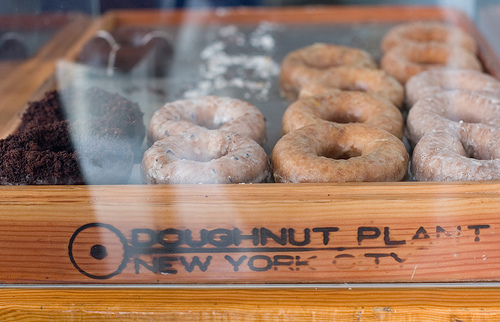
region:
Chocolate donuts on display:
[10, 51, 141, 227]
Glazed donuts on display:
[264, 37, 417, 229]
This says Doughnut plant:
[128, 212, 498, 274]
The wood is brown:
[11, 206, 118, 318]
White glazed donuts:
[144, 68, 286, 210]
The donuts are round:
[274, 37, 356, 186]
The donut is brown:
[6, 89, 129, 189]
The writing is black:
[109, 208, 402, 293]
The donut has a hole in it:
[311, 133, 386, 176]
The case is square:
[14, 6, 484, 295]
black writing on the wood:
[131, 210, 491, 251]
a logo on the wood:
[63, 213, 133, 282]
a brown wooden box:
[0, 0, 498, 279]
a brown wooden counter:
[0, 286, 497, 320]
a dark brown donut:
[0, 112, 141, 187]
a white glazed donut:
[136, 122, 266, 187]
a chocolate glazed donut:
[77, 21, 180, 76]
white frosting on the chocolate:
[101, 42, 122, 77]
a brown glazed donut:
[273, 117, 412, 192]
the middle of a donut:
[313, 137, 363, 164]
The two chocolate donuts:
[1, 84, 148, 189]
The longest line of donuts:
[378, 18, 498, 183]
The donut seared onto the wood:
[66, 222, 132, 282]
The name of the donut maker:
[127, 217, 494, 252]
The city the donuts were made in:
[124, 247, 414, 279]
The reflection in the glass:
[49, 0, 466, 279]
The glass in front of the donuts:
[0, 1, 499, 282]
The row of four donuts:
[272, 36, 412, 186]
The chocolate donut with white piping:
[79, 16, 175, 84]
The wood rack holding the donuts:
[0, 5, 499, 286]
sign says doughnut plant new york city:
[119, 208, 487, 293]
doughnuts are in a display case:
[13, 6, 493, 314]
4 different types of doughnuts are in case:
[2, 53, 498, 296]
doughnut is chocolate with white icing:
[60, 13, 215, 107]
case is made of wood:
[10, 29, 492, 268]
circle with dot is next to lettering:
[55, 217, 167, 289]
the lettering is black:
[119, 220, 498, 310]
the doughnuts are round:
[165, 6, 496, 190]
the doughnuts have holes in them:
[161, 6, 477, 221]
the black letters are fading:
[295, 224, 496, 296]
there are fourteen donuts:
[10, 8, 491, 277]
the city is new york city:
[34, 208, 481, 318]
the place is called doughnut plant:
[27, 164, 490, 311]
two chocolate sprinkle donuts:
[17, 59, 116, 193]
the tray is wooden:
[53, 29, 453, 239]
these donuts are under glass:
[26, 22, 458, 272]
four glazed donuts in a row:
[270, 13, 407, 225]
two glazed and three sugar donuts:
[386, 15, 498, 160]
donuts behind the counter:
[79, 17, 472, 214]